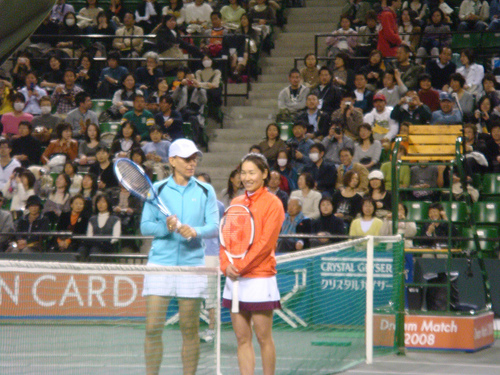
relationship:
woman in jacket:
[111, 136, 221, 373] [139, 172, 219, 267]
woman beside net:
[111, 136, 221, 373] [0, 261, 241, 372]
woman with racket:
[111, 136, 221, 373] [88, 153, 193, 235]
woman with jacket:
[111, 136, 221, 373] [139, 172, 219, 267]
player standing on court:
[217, 155, 286, 373] [15, 332, 139, 365]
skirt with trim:
[217, 273, 285, 317] [249, 303, 283, 313]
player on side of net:
[134, 130, 221, 374] [0, 236, 373, 374]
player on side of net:
[217, 155, 286, 373] [0, 236, 373, 374]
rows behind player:
[5, 0, 499, 251] [217, 155, 286, 373]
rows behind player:
[5, 0, 499, 251] [134, 130, 221, 374]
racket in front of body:
[216, 202, 256, 313] [219, 191, 286, 311]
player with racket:
[217, 155, 286, 373] [216, 202, 256, 313]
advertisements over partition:
[10, 229, 432, 344] [64, 262, 220, 272]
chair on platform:
[0, 0, 499, 265] [389, 160, 463, 305]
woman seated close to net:
[348, 196, 383, 233] [88, 227, 388, 364]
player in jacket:
[134, 130, 221, 374] [139, 172, 219, 267]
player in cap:
[134, 130, 221, 374] [172, 144, 194, 160]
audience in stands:
[11, 86, 147, 234] [4, 3, 491, 245]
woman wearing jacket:
[111, 136, 221, 373] [139, 172, 219, 267]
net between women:
[0, 236, 373, 374] [121, 137, 276, 374]